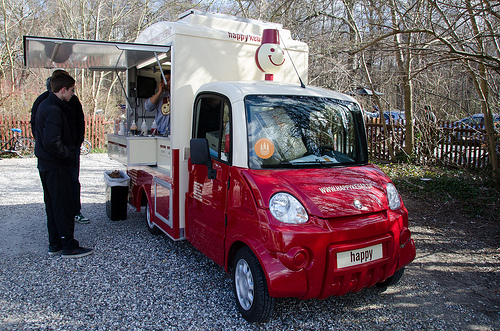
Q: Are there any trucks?
A: Yes, there is a truck.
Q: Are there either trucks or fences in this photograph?
A: Yes, there is a truck.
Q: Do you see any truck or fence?
A: Yes, there is a truck.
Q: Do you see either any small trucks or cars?
A: Yes, there is a small truck.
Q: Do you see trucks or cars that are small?
A: Yes, the truck is small.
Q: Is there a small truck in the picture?
A: Yes, there is a small truck.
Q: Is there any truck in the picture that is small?
A: Yes, there is a truck that is small.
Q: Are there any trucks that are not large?
A: Yes, there is a small truck.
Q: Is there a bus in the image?
A: No, there are no buses.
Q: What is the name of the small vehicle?
A: The vehicle is a truck.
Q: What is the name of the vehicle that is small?
A: The vehicle is a truck.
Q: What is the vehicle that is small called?
A: The vehicle is a truck.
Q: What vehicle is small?
A: The vehicle is a truck.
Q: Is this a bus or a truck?
A: This is a truck.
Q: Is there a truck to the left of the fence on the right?
A: Yes, there is a truck to the left of the fence.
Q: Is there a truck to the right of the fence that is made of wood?
A: No, the truck is to the left of the fence.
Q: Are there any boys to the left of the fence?
A: No, there is a truck to the left of the fence.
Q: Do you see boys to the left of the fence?
A: No, there is a truck to the left of the fence.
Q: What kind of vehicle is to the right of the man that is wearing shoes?
A: The vehicle is a truck.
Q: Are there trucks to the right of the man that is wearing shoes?
A: Yes, there is a truck to the right of the man.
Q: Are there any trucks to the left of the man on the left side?
A: No, the truck is to the right of the man.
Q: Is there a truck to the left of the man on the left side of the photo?
A: No, the truck is to the right of the man.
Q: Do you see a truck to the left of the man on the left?
A: No, the truck is to the right of the man.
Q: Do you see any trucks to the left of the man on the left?
A: No, the truck is to the right of the man.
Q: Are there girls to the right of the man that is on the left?
A: No, there is a truck to the right of the man.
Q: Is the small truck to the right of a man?
A: Yes, the truck is to the right of a man.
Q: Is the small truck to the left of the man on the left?
A: No, the truck is to the right of the man.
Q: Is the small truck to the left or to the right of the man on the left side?
A: The truck is to the right of the man.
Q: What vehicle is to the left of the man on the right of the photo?
A: The vehicle is a truck.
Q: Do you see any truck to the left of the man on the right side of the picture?
A: Yes, there is a truck to the left of the man.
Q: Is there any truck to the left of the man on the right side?
A: Yes, there is a truck to the left of the man.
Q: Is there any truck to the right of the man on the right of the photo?
A: No, the truck is to the left of the man.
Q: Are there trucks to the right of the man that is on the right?
A: No, the truck is to the left of the man.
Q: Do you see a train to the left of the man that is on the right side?
A: No, there is a truck to the left of the man.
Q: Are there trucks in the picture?
A: Yes, there is a truck.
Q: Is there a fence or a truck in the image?
A: Yes, there is a truck.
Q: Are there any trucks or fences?
A: Yes, there is a truck.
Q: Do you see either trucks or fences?
A: Yes, there is a truck.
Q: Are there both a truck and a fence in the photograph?
A: Yes, there are both a truck and a fence.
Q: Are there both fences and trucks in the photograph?
A: Yes, there are both a truck and a fence.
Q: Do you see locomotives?
A: No, there are no locomotives.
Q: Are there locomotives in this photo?
A: No, there are no locomotives.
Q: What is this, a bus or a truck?
A: This is a truck.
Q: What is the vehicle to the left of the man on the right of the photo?
A: The vehicle is a truck.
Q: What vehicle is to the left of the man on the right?
A: The vehicle is a truck.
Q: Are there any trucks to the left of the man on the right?
A: Yes, there is a truck to the left of the man.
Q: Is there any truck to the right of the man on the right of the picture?
A: No, the truck is to the left of the man.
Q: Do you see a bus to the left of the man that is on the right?
A: No, there is a truck to the left of the man.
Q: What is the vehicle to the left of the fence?
A: The vehicle is a truck.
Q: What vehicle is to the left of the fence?
A: The vehicle is a truck.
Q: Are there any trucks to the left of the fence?
A: Yes, there is a truck to the left of the fence.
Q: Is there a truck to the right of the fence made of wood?
A: No, the truck is to the left of the fence.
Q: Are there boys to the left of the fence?
A: No, there is a truck to the left of the fence.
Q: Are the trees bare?
A: Yes, the trees are bare.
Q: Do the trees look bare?
A: Yes, the trees are bare.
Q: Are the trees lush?
A: No, the trees are bare.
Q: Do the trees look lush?
A: No, the trees are bare.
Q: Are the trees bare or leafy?
A: The trees are bare.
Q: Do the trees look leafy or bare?
A: The trees are bare.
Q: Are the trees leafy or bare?
A: The trees are bare.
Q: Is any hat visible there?
A: Yes, there is a hat.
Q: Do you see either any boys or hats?
A: Yes, there is a hat.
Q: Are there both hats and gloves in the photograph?
A: No, there is a hat but no gloves.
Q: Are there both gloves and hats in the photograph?
A: No, there is a hat but no gloves.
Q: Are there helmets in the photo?
A: No, there are no helmets.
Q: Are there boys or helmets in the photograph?
A: No, there are no helmets or boys.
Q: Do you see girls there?
A: No, there are no girls.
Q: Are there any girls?
A: No, there are no girls.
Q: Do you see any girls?
A: No, there are no girls.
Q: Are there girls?
A: No, there are no girls.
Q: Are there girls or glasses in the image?
A: No, there are no girls or glasses.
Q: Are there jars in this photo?
A: No, there are no jars.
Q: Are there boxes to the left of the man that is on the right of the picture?
A: Yes, there are boxes to the left of the man.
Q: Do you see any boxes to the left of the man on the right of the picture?
A: Yes, there are boxes to the left of the man.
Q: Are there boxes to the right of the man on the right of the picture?
A: No, the boxes are to the left of the man.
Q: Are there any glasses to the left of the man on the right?
A: No, there are boxes to the left of the man.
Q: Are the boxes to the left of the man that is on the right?
A: Yes, the boxes are to the left of the man.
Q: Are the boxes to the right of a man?
A: No, the boxes are to the left of a man.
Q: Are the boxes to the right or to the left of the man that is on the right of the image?
A: The boxes are to the left of the man.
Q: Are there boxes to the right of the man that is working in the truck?
A: Yes, there are boxes to the right of the man.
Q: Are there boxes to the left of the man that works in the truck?
A: No, the boxes are to the right of the man.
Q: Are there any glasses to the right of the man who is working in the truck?
A: No, there are boxes to the right of the man.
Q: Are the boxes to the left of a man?
A: No, the boxes are to the right of a man.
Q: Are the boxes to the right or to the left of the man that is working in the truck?
A: The boxes are to the right of the man.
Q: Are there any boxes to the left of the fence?
A: Yes, there are boxes to the left of the fence.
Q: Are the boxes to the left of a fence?
A: Yes, the boxes are to the left of a fence.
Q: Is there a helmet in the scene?
A: No, there are no helmets.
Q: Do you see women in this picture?
A: No, there are no women.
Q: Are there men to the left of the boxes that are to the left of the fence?
A: Yes, there is a man to the left of the boxes.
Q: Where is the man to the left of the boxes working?
A: The man is working in the truck.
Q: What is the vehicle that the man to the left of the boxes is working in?
A: The vehicle is a truck.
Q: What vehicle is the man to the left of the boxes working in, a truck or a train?
A: The man is working in a truck.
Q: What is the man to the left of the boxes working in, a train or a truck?
A: The man is working in a truck.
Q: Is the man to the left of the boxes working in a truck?
A: Yes, the man is working in a truck.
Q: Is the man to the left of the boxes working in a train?
A: No, the man is working in a truck.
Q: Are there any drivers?
A: No, there are no drivers.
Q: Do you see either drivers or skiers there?
A: No, there are no drivers or skiers.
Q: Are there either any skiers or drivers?
A: No, there are no drivers or skiers.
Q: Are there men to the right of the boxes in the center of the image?
A: Yes, there is a man to the right of the boxes.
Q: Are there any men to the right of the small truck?
A: Yes, there is a man to the right of the truck.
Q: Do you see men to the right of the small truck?
A: Yes, there is a man to the right of the truck.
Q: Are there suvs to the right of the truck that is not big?
A: No, there is a man to the right of the truck.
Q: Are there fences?
A: Yes, there is a fence.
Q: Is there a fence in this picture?
A: Yes, there is a fence.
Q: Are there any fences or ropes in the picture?
A: Yes, there is a fence.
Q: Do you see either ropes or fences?
A: Yes, there is a fence.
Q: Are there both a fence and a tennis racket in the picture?
A: No, there is a fence but no rackets.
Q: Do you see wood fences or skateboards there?
A: Yes, there is a wood fence.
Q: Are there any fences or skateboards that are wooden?
A: Yes, the fence is wooden.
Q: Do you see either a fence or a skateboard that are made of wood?
A: Yes, the fence is made of wood.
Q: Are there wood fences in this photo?
A: Yes, there is a wood fence.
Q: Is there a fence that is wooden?
A: Yes, there is a fence that is wooden.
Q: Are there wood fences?
A: Yes, there is a fence that is made of wood.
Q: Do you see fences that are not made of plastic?
A: Yes, there is a fence that is made of wood.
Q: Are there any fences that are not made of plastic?
A: Yes, there is a fence that is made of wood.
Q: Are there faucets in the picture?
A: No, there are no faucets.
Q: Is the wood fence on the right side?
A: Yes, the fence is on the right of the image.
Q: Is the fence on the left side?
A: No, the fence is on the right of the image.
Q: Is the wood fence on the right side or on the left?
A: The fence is on the right of the image.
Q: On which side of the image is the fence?
A: The fence is on the right of the image.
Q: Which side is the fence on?
A: The fence is on the right of the image.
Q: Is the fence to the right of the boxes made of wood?
A: Yes, the fence is made of wood.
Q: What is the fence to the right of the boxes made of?
A: The fence is made of wood.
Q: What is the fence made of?
A: The fence is made of wood.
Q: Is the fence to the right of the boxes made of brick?
A: No, the fence is made of wood.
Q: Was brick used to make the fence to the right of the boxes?
A: No, the fence is made of wood.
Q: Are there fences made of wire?
A: No, there is a fence but it is made of wood.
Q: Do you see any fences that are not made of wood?
A: No, there is a fence but it is made of wood.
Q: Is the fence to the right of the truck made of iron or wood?
A: The fence is made of wood.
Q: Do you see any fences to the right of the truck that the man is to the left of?
A: Yes, there is a fence to the right of the truck.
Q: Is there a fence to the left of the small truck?
A: No, the fence is to the right of the truck.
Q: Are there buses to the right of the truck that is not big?
A: No, there is a fence to the right of the truck.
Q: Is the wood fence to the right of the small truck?
A: Yes, the fence is to the right of the truck.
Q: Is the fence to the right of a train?
A: No, the fence is to the right of the truck.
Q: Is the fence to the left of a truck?
A: No, the fence is to the right of a truck.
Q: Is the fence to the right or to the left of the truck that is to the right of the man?
A: The fence is to the right of the truck.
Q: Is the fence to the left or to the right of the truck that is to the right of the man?
A: The fence is to the right of the truck.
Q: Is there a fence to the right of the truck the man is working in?
A: Yes, there is a fence to the right of the truck.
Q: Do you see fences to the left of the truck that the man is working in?
A: No, the fence is to the right of the truck.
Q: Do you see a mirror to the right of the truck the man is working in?
A: No, there is a fence to the right of the truck.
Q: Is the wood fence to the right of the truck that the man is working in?
A: Yes, the fence is to the right of the truck.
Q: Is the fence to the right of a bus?
A: No, the fence is to the right of the truck.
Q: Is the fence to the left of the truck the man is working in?
A: No, the fence is to the right of the truck.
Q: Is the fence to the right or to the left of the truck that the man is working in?
A: The fence is to the right of the truck.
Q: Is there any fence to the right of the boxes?
A: Yes, there is a fence to the right of the boxes.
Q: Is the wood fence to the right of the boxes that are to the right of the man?
A: Yes, the fence is to the right of the boxes.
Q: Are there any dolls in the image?
A: Yes, there is a doll.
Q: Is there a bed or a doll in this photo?
A: Yes, there is a doll.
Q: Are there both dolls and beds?
A: No, there is a doll but no beds.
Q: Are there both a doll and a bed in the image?
A: No, there is a doll but no beds.